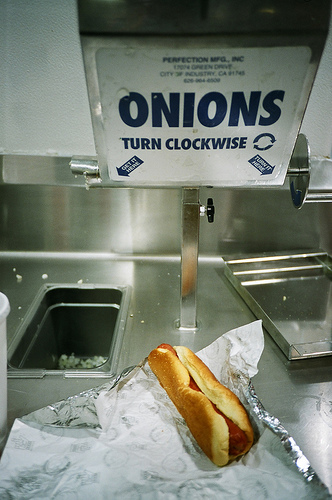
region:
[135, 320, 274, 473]
a hot dog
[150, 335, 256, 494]
the hot dog is on a bun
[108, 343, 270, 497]
the hot dog is laying on paper wrapping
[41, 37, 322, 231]
the onion machine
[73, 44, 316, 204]
apparently it makes the onions perfect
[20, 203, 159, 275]
the area is made out of stainless steel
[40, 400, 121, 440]
the wrapping paper has a foil side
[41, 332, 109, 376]
only a few onions remain in the bin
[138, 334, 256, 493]
the hot dog look yummy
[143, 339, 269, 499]
the bun is nearly yellow in color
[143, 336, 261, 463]
hotdog is encased in bun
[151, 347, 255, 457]
the hotdog is on the foil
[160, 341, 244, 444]
the sausage is red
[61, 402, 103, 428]
the foil is silver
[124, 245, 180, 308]
the surface is shiny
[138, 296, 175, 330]
the surface is mettalic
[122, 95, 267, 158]
the sign says onions turn clockwise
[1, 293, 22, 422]
the container is white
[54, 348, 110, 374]
there is food parcticles in the sink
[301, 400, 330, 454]
the light is shining on the surface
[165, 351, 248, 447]
the hotdog has no mastard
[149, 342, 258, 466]
The bun of the hot dog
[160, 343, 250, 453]
The hot dog in the bun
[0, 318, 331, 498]
The wrapper of the hot dog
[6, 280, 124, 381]
The open bucket with onions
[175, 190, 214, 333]
The pole holding up the onion box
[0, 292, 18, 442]
The soda cup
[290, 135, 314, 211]
The dial on the onion box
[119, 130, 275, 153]
The directions on the onion box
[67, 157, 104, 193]
The shoot the onions come out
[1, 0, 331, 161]
The white wall behind the onion box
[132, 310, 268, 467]
the hotdog is cooked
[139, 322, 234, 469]
the bread is brown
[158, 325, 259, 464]
the meat is red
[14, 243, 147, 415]
the counter is metal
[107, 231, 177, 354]
the metal is silver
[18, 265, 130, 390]
the tray is plastic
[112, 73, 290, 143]
the text is blue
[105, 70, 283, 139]
the text says onions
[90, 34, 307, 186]
the sign is white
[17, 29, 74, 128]
the wall is white